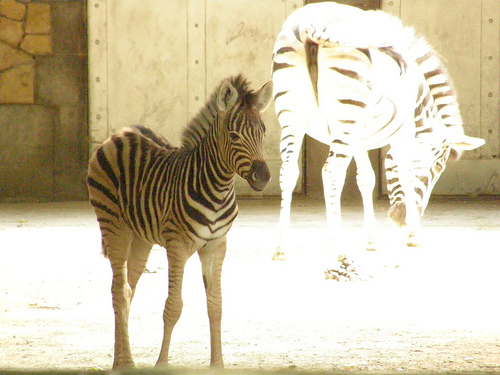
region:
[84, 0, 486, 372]
two zebra in the picture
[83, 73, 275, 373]
black and white zebra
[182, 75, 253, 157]
zebra have white and black mane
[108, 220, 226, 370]
white underside of smaller zebra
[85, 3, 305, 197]
white door behind zebra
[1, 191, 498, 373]
animals are standing in dirt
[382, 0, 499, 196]
large white door right of zebra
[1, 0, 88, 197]
grey and tan stone wall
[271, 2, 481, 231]
larger zebra grazing in sunlight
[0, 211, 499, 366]
natural light brightens dirt floor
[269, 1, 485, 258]
zebra grazing on rocky ground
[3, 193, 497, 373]
Rocky dirt road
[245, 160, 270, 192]
black snout on zebra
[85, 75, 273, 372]
zebra is walking away from a building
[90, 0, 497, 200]
white wall of a building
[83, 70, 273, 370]
young zebra standing on a dirt road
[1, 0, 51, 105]
mosaic art piece on wall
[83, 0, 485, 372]
two black and white zebras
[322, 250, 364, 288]
pile of rocks on a dirt road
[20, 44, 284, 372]
Baby zebra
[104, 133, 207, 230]
Black and white striped body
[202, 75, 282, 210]
Head of the baby zebra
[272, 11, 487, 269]
Mother of the baby zebra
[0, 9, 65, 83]
Stone wall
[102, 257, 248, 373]
Four legs of the baby zebra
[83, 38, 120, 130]
Rivets on the wall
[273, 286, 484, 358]
Ground of the zebra habitat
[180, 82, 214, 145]
Mane of the baby zebra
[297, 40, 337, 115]
Tail of the mother zebra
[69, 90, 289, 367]
a baby zebra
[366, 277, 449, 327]
bright sunlight shining on the ground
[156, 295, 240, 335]
knobby knees on a zebra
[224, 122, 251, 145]
black eye on head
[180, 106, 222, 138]
fluffy black and white mane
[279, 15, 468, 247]
an adult zebra grazing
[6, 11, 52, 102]
stones on a cement wall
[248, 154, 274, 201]
a black snout on a zebra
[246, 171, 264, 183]
a large nostril in a snout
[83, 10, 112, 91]
metal screws in the wall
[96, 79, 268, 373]
a young zebra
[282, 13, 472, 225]
an adult zebra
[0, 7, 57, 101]
some wall decorations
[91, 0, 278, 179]
a big door in the back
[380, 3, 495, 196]
a smaller door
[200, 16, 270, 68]
some scratching on a door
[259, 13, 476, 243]
a glowing zebra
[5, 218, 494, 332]
some very bright sunlight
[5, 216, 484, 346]
dirt on the ground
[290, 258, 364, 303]
a small rock in the sunlight